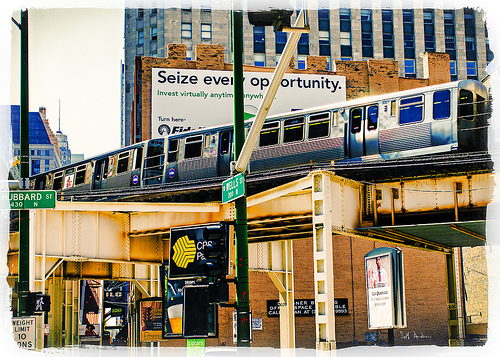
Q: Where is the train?
A: Elevated.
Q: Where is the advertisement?
A: Side of building.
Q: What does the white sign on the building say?
A: Seize every opportunity.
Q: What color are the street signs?
A: Green.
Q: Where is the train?
A: On the tracks.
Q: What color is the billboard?
A: White, green, and blue.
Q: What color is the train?
A: Silver.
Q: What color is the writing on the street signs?
A: White.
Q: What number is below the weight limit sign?
A: 10.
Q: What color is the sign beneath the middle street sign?
A: Black and yellow.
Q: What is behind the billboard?
A: A building.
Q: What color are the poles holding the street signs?
A: Green.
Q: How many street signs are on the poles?
A: 2.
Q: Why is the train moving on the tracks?
A: To reach destination.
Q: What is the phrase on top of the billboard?
A: Seize every opportunity.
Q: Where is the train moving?
A: Railroad tracks on a bridge.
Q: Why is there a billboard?
A: For advertisement.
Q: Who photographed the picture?
A: Tourist.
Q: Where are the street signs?
A: Green poles.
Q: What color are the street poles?
A: Green.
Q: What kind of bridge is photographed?
A: Railroad bridge.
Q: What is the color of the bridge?
A: Brown and black.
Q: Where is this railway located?
A: In city.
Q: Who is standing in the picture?
A: No one.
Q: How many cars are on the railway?
A: Three.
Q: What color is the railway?
A: Blue and silver.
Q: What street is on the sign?
A: Hubbard.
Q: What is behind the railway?
A: A building.